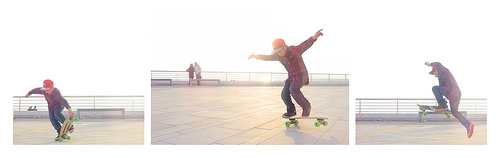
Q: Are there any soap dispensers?
A: No, there are no soap dispensers.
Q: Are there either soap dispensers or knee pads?
A: No, there are no soap dispensers or knee pads.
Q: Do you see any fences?
A: Yes, there is a fence.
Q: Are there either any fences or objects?
A: Yes, there is a fence.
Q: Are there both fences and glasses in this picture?
A: No, there is a fence but no glasses.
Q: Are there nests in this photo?
A: No, there are no nests.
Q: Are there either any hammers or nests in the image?
A: No, there are no nests or hammers.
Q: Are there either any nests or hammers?
A: No, there are no nests or hammers.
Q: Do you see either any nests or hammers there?
A: No, there are no nests or hammers.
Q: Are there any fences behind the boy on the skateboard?
A: Yes, there is a fence behind the boy.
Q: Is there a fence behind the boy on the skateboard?
A: Yes, there is a fence behind the boy.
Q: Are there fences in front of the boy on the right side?
A: No, the fence is behind the boy.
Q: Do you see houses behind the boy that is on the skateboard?
A: No, there is a fence behind the boy.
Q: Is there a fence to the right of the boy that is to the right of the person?
A: Yes, there is a fence to the right of the boy.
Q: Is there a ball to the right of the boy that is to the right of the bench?
A: No, there is a fence to the right of the boy.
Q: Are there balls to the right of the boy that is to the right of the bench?
A: No, there is a fence to the right of the boy.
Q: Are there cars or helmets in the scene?
A: No, there are no cars or helmets.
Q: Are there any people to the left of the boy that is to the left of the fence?
A: Yes, there is a person to the left of the boy.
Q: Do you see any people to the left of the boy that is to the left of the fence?
A: Yes, there is a person to the left of the boy.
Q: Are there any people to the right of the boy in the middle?
A: No, the person is to the left of the boy.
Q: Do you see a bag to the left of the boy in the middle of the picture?
A: No, there is a person to the left of the boy.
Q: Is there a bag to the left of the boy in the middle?
A: No, there is a person to the left of the boy.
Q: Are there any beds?
A: No, there are no beds.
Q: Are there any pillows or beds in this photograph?
A: No, there are no beds or pillows.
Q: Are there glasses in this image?
A: No, there are no glasses.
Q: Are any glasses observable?
A: No, there are no glasses.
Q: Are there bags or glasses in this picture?
A: No, there are no glasses or bags.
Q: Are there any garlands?
A: No, there are no garlands.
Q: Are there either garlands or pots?
A: No, there are no garlands or pots.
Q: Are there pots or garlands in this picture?
A: No, there are no garlands or pots.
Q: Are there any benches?
A: Yes, there is a bench.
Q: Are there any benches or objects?
A: Yes, there is a bench.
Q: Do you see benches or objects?
A: Yes, there is a bench.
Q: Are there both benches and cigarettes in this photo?
A: No, there is a bench but no cigarettes.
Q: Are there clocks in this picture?
A: No, there are no clocks.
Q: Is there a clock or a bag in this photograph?
A: No, there are no clocks or bags.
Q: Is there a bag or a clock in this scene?
A: No, there are no clocks or bags.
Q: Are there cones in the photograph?
A: No, there are no cones.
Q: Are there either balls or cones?
A: No, there are no cones or balls.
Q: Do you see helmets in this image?
A: No, there are no helmets.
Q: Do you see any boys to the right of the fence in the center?
A: Yes, there is a boy to the right of the fence.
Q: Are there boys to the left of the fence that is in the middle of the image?
A: No, the boy is to the right of the fence.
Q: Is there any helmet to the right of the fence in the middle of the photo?
A: No, there is a boy to the right of the fence.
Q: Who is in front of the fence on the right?
A: The boy is in front of the fence.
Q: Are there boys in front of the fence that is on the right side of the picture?
A: Yes, there is a boy in front of the fence.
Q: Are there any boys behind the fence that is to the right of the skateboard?
A: No, the boy is in front of the fence.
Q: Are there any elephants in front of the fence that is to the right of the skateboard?
A: No, there is a boy in front of the fence.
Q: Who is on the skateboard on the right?
A: The boy is on the skateboard.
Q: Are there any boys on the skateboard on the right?
A: Yes, there is a boy on the skateboard.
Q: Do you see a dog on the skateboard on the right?
A: No, there is a boy on the skateboard.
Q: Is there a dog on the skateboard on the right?
A: No, there is a boy on the skateboard.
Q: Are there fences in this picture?
A: Yes, there is a fence.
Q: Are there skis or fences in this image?
A: Yes, there is a fence.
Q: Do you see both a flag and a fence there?
A: No, there is a fence but no flags.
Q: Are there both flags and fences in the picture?
A: No, there is a fence but no flags.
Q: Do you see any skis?
A: No, there are no skis.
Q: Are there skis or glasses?
A: No, there are no skis or glasses.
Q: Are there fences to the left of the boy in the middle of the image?
A: Yes, there is a fence to the left of the boy.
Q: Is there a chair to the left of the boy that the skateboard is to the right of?
A: No, there is a fence to the left of the boy.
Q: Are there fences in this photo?
A: Yes, there is a fence.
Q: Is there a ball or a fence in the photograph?
A: Yes, there is a fence.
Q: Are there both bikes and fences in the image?
A: No, there is a fence but no bikes.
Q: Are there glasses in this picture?
A: No, there are no glasses.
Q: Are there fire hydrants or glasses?
A: No, there are no glasses or fire hydrants.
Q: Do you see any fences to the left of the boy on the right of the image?
A: Yes, there is a fence to the left of the boy.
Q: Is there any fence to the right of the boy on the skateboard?
A: No, the fence is to the left of the boy.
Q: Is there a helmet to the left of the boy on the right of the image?
A: No, there is a fence to the left of the boy.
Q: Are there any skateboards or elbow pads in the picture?
A: Yes, there is a skateboard.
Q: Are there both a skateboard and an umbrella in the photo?
A: No, there is a skateboard but no umbrellas.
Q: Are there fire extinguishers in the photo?
A: No, there are no fire extinguishers.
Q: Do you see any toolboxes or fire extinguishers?
A: No, there are no fire extinguishers or toolboxes.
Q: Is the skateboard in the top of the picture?
A: No, the skateboard is in the bottom of the image.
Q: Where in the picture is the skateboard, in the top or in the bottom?
A: The skateboard is in the bottom of the image.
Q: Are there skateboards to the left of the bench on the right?
A: Yes, there is a skateboard to the left of the bench.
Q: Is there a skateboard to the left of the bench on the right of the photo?
A: Yes, there is a skateboard to the left of the bench.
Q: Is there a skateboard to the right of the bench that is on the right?
A: No, the skateboard is to the left of the bench.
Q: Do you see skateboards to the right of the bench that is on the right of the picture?
A: No, the skateboard is to the left of the bench.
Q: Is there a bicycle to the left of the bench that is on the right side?
A: No, there is a skateboard to the left of the bench.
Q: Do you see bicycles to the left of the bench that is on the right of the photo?
A: No, there is a skateboard to the left of the bench.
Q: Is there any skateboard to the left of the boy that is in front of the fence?
A: Yes, there is a skateboard to the left of the boy.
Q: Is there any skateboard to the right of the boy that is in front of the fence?
A: No, the skateboard is to the left of the boy.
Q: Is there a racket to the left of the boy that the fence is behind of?
A: No, there is a skateboard to the left of the boy.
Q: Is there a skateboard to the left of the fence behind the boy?
A: Yes, there is a skateboard to the left of the fence.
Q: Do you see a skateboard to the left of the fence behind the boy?
A: Yes, there is a skateboard to the left of the fence.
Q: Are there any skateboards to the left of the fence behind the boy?
A: Yes, there is a skateboard to the left of the fence.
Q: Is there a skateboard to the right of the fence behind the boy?
A: No, the skateboard is to the left of the fence.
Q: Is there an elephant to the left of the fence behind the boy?
A: No, there is a skateboard to the left of the fence.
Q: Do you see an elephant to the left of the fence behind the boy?
A: No, there is a skateboard to the left of the fence.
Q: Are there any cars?
A: No, there are no cars.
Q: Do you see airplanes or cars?
A: No, there are no cars or airplanes.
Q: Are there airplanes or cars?
A: No, there are no cars or airplanes.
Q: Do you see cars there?
A: No, there are no cars.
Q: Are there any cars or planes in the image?
A: No, there are no cars or planes.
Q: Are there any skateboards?
A: Yes, there is a skateboard.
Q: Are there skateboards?
A: Yes, there is a skateboard.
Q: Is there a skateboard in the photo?
A: Yes, there is a skateboard.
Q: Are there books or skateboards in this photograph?
A: Yes, there is a skateboard.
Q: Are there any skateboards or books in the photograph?
A: Yes, there is a skateboard.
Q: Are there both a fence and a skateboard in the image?
A: Yes, there are both a skateboard and a fence.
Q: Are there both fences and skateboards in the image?
A: Yes, there are both a skateboard and a fence.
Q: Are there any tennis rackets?
A: No, there are no tennis rackets.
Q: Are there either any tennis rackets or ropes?
A: No, there are no tennis rackets or ropes.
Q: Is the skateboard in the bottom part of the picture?
A: Yes, the skateboard is in the bottom of the image.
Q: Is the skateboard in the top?
A: No, the skateboard is in the bottom of the image.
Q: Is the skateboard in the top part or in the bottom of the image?
A: The skateboard is in the bottom of the image.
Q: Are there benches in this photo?
A: Yes, there is a bench.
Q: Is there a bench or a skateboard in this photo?
A: Yes, there is a bench.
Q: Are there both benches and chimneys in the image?
A: No, there is a bench but no chimneys.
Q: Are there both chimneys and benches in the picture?
A: No, there is a bench but no chimneys.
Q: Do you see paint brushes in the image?
A: No, there are no paint brushes.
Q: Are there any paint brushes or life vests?
A: No, there are no paint brushes or life vests.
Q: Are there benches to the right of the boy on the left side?
A: Yes, there is a bench to the right of the boy.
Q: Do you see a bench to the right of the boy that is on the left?
A: Yes, there is a bench to the right of the boy.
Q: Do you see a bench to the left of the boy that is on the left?
A: No, the bench is to the right of the boy.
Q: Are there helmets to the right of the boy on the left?
A: No, there is a bench to the right of the boy.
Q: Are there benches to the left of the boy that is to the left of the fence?
A: Yes, there is a bench to the left of the boy.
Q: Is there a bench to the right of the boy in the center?
A: No, the bench is to the left of the boy.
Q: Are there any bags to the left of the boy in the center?
A: No, there is a bench to the left of the boy.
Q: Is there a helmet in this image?
A: No, there are no helmets.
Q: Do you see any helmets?
A: No, there are no helmets.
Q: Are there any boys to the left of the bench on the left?
A: Yes, there is a boy to the left of the bench.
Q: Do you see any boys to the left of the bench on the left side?
A: Yes, there is a boy to the left of the bench.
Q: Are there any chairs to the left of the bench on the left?
A: No, there is a boy to the left of the bench.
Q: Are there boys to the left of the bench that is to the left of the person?
A: Yes, there is a boy to the left of the bench.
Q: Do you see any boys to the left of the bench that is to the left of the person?
A: Yes, there is a boy to the left of the bench.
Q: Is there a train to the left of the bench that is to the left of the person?
A: No, there is a boy to the left of the bench.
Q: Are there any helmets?
A: No, there are no helmets.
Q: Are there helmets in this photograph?
A: No, there are no helmets.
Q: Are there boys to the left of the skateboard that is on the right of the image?
A: Yes, there is a boy to the left of the skateboard.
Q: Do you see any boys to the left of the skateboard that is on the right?
A: Yes, there is a boy to the left of the skateboard.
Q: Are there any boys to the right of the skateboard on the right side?
A: No, the boy is to the left of the skateboard.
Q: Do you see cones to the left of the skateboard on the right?
A: No, there is a boy to the left of the skateboard.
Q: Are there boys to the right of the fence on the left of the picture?
A: Yes, there is a boy to the right of the fence.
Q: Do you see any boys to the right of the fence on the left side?
A: Yes, there is a boy to the right of the fence.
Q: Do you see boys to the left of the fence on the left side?
A: No, the boy is to the right of the fence.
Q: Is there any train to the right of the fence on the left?
A: No, there is a boy to the right of the fence.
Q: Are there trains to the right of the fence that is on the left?
A: No, there is a boy to the right of the fence.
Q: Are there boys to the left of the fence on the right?
A: Yes, there is a boy to the left of the fence.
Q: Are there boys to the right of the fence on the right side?
A: No, the boy is to the left of the fence.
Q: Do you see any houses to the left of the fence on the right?
A: No, there is a boy to the left of the fence.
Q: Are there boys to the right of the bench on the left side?
A: Yes, there is a boy to the right of the bench.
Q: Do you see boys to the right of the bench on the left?
A: Yes, there is a boy to the right of the bench.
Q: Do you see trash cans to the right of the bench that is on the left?
A: No, there is a boy to the right of the bench.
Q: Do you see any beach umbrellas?
A: No, there are no beach umbrellas.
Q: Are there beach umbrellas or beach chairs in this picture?
A: No, there are no beach umbrellas or beach chairs.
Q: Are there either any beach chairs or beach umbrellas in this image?
A: No, there are no beach umbrellas or beach chairs.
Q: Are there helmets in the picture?
A: No, there are no helmets.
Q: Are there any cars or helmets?
A: No, there are no helmets or cars.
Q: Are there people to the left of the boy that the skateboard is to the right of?
A: Yes, there is a person to the left of the boy.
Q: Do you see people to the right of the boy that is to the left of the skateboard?
A: No, the person is to the left of the boy.